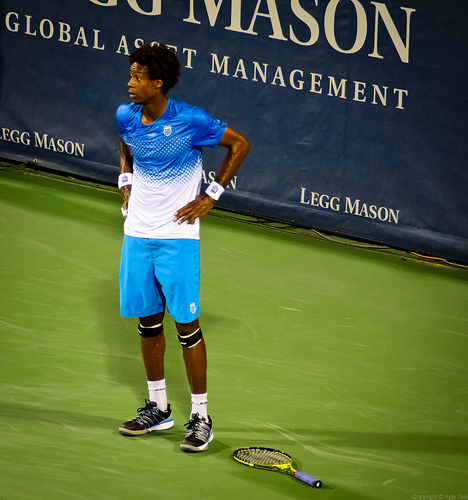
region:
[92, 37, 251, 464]
A man with his hands on his hips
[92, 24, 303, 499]
A tennis player with his hands on his hips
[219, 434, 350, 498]
A tennis racquet on the ground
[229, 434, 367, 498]
A tennis racquet on the court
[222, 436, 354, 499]
A yellow tennis racquet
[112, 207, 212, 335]
A man wearing blue shorts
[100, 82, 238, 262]
A man wearing a blue and white shirt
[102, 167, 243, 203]
A man with white wristbands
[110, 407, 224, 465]
A man wearing tennis shoes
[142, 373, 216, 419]
A man wearing white socks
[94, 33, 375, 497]
a man playing tennis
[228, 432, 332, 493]
a yellow and black racket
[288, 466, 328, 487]
the handle of a tennis racket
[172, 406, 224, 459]
a silver and black tennis shoe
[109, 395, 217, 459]
a pair of tennis shoes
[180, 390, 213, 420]
a white tennis sock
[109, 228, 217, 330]
a pair of tennis shorts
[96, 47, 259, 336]
a man wearing a tennis outfit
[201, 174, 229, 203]
a blue and white wrist band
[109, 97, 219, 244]
a blue and white tennis shirt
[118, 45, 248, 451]
Tennis player with a light blue and with uniform.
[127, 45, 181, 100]
Black man with black hair.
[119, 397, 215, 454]
Tennis shoes black and blue.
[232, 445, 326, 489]
Racket in the ground.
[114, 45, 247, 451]
Black man on a ground.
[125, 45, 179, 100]
Black man with a angry feeling.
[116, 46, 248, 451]
Black man with his hand in the waist.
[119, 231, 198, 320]
The tennis player is wearing light blue shorts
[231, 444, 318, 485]
Yellow and blue racket.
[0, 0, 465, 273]
Advertisement in blue behind the tennis player.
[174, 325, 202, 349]
Black and white knee band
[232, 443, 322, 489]
Yellow and black tennis racket on ground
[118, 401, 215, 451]
Pair of black and blue sneakers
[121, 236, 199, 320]
Pair of blue shorts with white logo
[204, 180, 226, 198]
White wristband with purple logo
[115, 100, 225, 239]
Silk blue and white t-shirt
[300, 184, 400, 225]
Legg Mason written on side of wall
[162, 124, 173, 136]
Small white logo on front of shirt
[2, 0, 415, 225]
Advertisement on side of blue wall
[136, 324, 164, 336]
Black and white knee band on player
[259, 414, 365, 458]
white lines on the green court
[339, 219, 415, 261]
edge of tennis court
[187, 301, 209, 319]
white logo on blue shorts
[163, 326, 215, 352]
black and white knee pad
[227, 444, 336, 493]
tennis racket on court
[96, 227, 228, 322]
blue tennis short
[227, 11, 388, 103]
words on blue wall covering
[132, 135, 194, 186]
white spots on the blue and white shirt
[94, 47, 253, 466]
Gael Monfils standing on court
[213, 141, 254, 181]
veins in Gael's hand